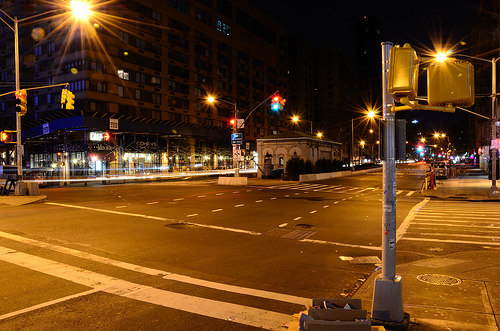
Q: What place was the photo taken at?
A: It was taken at the street.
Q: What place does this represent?
A: It represents the street.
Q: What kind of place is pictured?
A: It is a street.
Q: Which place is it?
A: It is a street.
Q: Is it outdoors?
A: Yes, it is outdoors.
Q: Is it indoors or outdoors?
A: It is outdoors.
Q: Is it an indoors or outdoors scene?
A: It is outdoors.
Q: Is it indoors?
A: No, it is outdoors.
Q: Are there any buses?
A: No, there are no buses.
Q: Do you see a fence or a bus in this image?
A: No, there are no buses or fences.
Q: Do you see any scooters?
A: No, there are no scooters.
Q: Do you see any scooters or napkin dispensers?
A: No, there are no scooters or napkin dispensers.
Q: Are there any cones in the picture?
A: No, there are no cones.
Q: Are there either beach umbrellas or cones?
A: No, there are no cones or beach umbrellas.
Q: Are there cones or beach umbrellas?
A: No, there are no cones or beach umbrellas.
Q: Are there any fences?
A: No, there are no fences.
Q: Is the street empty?
A: Yes, the street is empty.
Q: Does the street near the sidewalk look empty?
A: Yes, the street is empty.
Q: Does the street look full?
A: No, the street is empty.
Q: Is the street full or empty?
A: The street is empty.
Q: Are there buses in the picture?
A: No, there are no buses.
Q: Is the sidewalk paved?
A: Yes, the sidewalk is paved.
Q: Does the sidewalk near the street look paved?
A: Yes, the sidewalk is paved.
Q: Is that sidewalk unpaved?
A: No, the sidewalk is paved.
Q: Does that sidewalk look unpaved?
A: No, the sidewalk is paved.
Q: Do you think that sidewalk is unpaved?
A: No, the sidewalk is paved.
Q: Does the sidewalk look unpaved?
A: No, the sidewalk is paved.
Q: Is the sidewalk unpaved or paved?
A: The sidewalk is paved.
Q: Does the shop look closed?
A: Yes, the shop is closed.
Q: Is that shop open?
A: No, the shop is closed.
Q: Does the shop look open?
A: No, the shop is closed.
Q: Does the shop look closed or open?
A: The shop is closed.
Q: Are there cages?
A: No, there are no cages.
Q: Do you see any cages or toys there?
A: No, there are no cages or toys.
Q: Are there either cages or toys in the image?
A: No, there are no cages or toys.